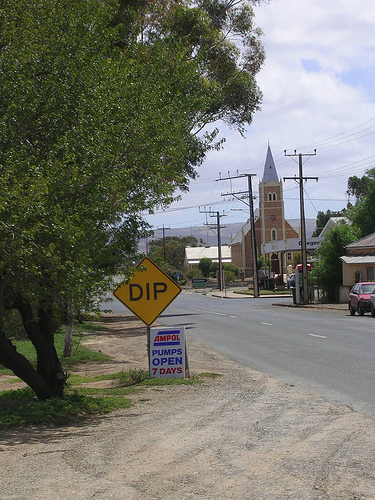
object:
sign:
[112, 257, 182, 326]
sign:
[146, 326, 189, 378]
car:
[347, 281, 375, 317]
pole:
[299, 154, 309, 306]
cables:
[316, 132, 375, 152]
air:
[264, 75, 324, 135]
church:
[228, 137, 301, 278]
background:
[3, 0, 375, 500]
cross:
[267, 139, 270, 146]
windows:
[269, 193, 272, 201]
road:
[0, 288, 375, 500]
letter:
[127, 283, 144, 304]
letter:
[145, 282, 150, 302]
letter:
[152, 280, 167, 300]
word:
[151, 356, 182, 366]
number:
[152, 368, 158, 376]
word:
[159, 366, 182, 375]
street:
[102, 282, 375, 412]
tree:
[0, 0, 265, 404]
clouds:
[260, 60, 374, 120]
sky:
[137, 0, 374, 220]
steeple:
[260, 139, 280, 183]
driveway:
[0, 315, 375, 500]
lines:
[307, 333, 327, 338]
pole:
[147, 326, 151, 377]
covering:
[261, 236, 330, 254]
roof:
[184, 246, 237, 264]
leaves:
[130, 78, 135, 86]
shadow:
[86, 313, 201, 323]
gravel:
[0, 323, 375, 500]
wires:
[313, 154, 375, 175]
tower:
[256, 141, 285, 255]